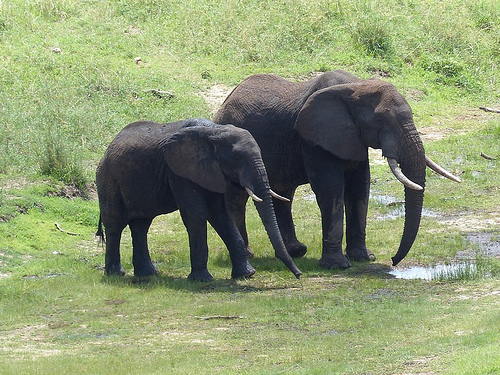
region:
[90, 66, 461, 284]
elephant next to elephant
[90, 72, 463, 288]
small elephant next to large elephant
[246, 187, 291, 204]
the elephants have tusks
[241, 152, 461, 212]
the tusks are white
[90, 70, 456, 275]
the elephants are walking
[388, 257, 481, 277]
the elephant drinks from a puddle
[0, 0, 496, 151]
a grassy hill behind the elephants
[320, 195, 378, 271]
dried mud on the front legs of the larger elephant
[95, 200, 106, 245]
the smaller elephant's tail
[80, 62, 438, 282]
the elephants are gray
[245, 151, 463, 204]
The elephants have white tusks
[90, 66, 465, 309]
There are 2 gray elephants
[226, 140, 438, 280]
The elephants trunk are long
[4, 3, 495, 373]
The grass is green and patchy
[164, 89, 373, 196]
The elephants have large flappy ears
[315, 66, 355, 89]
The large elephant has a hump on his back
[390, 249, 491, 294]
The water puddle is small and reflective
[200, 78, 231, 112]
The dirt is light brown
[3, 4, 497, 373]
The scene is outdoors and sunny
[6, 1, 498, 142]
The hill is grassy and green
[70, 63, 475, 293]
two elephants standing side by side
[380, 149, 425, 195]
a large white tusk on the larger elephant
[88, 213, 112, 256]
a small stringy tail on the smaller elephant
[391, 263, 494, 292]
a small puddle of water on the ground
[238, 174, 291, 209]
a set of white tusks on the smaller elephant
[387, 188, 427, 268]
a long trunk hanging on the bigger elephant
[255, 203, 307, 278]
the trunk on the smaller elephant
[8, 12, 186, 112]
long green grasses with a few rocks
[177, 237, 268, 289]
two large feet of the elephant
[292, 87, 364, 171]
the elephant's gigantic ear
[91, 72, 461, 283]
Two gray elephants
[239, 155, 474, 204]
Both elephants have tusks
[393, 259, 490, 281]
A puddle of water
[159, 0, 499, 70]
An area with dry green grass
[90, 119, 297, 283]
A smaller elephant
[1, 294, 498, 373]
The grass is short with patches of dirt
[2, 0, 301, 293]
The grassy area behind the elephants goes uphill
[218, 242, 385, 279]
Shadows around the elephants feet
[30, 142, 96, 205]
A bunch of rough grass with dirt underneath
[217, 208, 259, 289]
The elephant lifts his front leg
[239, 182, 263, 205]
White tusk on elephant.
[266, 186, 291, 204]
White tusk on elephant.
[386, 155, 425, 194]
White tusk on elephant.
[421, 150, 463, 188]
White tusk on elephant.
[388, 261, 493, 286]
Puddle in front of elephant.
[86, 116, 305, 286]
Baby elephant next to adult.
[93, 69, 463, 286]
Elephants standing in grass.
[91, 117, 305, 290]
Small dark grey elephant.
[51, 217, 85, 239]
Branch in the weeds.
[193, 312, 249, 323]
Branch on the ground.